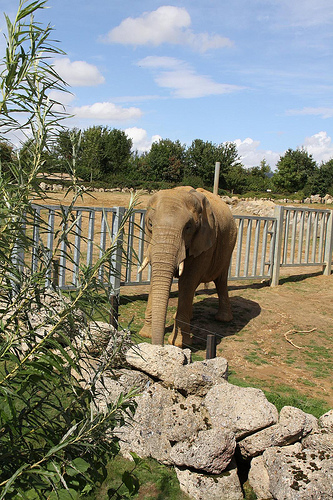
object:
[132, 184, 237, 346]
elephant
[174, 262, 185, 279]
left tusk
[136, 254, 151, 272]
right tusk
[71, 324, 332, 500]
boulders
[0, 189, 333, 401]
ground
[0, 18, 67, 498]
bush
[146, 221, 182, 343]
trunk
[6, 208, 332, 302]
fence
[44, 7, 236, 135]
clouds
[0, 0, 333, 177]
sky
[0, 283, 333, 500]
rocks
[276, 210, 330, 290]
gate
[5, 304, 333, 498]
wall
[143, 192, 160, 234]
ear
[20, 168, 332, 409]
enclosure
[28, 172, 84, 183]
house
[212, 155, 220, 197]
post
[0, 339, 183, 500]
grass